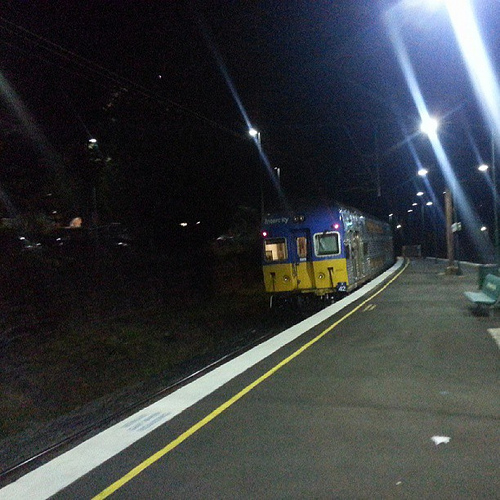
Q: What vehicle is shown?
A: Train.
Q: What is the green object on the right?
A: Bench.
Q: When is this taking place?
A: Night time.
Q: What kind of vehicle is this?
A: Train.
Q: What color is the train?
A: Blue and yellow.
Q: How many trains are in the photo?
A: One.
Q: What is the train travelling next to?
A: Platform.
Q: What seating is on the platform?
A: Bench.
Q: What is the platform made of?
A: Concrete.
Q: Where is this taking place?
A: Near a train track.